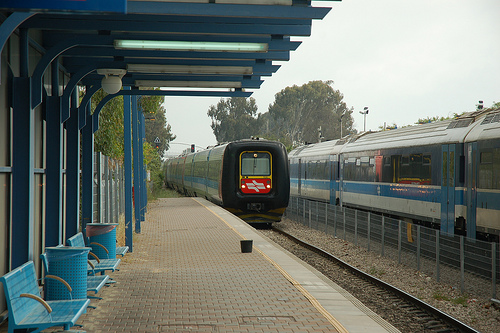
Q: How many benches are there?
A: 4.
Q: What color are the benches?
A: Blue.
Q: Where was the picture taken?
A: At a train station.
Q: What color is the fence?
A: Gray.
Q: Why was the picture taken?
A: To show the train station.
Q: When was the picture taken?
A: In the day time.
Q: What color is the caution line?
A: Yellow.